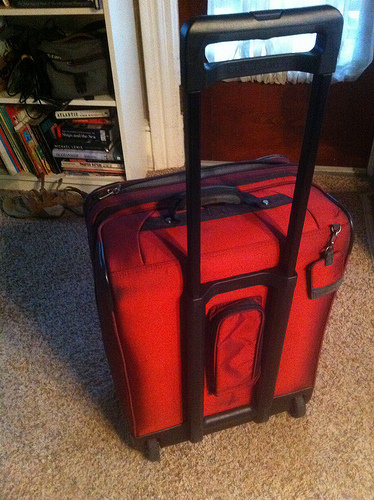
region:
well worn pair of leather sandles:
[1, 174, 87, 222]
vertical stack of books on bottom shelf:
[51, 108, 125, 176]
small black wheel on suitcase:
[145, 440, 162, 462]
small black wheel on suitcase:
[293, 397, 305, 417]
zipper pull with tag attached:
[323, 221, 342, 267]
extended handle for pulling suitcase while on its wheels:
[179, 8, 340, 273]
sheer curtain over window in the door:
[204, 1, 372, 82]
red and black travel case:
[78, 0, 365, 466]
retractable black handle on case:
[174, 1, 347, 444]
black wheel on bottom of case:
[286, 383, 315, 423]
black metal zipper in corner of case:
[320, 220, 344, 269]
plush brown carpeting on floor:
[1, 163, 372, 499]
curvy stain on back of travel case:
[214, 305, 257, 411]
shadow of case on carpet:
[0, 168, 135, 445]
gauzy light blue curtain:
[202, 0, 373, 83]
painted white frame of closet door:
[135, 0, 187, 173]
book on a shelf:
[52, 107, 110, 120]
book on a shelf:
[71, 116, 118, 125]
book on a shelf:
[49, 120, 115, 140]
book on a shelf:
[51, 147, 120, 162]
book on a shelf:
[60, 160, 120, 167]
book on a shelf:
[28, 113, 61, 172]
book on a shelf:
[18, 124, 44, 175]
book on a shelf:
[0, 108, 28, 168]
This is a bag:
[86, 146, 363, 476]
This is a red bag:
[66, 123, 347, 486]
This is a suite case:
[79, 115, 352, 482]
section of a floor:
[15, 361, 97, 496]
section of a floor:
[143, 455, 308, 497]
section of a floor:
[254, 421, 358, 495]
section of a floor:
[10, 226, 88, 388]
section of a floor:
[320, 333, 363, 497]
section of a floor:
[60, 440, 306, 497]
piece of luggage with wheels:
[82, 6, 353, 460]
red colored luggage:
[83, 6, 353, 461]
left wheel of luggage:
[145, 437, 161, 461]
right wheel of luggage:
[288, 392, 306, 415]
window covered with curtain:
[205, 2, 372, 84]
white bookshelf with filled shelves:
[2, 1, 146, 191]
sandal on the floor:
[6, 176, 65, 219]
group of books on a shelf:
[1, 103, 122, 177]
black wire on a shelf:
[1, 37, 46, 119]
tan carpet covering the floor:
[0, 163, 372, 498]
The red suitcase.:
[75, 157, 354, 455]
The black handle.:
[180, 8, 319, 224]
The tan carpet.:
[7, 172, 367, 477]